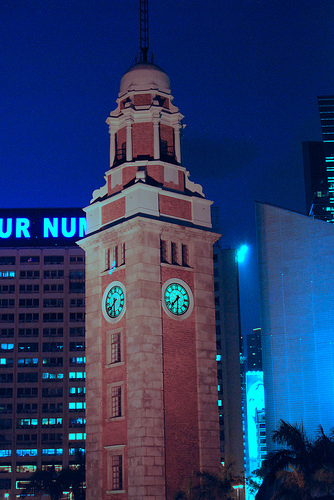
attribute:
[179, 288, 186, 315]
numbers — roman 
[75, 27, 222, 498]
tower — brick, tall, illuminated, clock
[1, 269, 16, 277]
light — on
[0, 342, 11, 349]
light — on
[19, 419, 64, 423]
light — on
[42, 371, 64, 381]
light — on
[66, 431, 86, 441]
light — on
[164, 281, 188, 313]
face — white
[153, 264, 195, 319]
clock — round, lighted, tower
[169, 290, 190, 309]
clock — illuminated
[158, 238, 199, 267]
three windows — lit, dark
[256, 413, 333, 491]
tree — palm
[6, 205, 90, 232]
sign — neon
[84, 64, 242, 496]
tall tower — brick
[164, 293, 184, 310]
hand on clock — hour, minute, black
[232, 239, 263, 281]
light — shining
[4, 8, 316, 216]
sky — blue, clear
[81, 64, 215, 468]
building — tall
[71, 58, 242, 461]
tower — red, brick